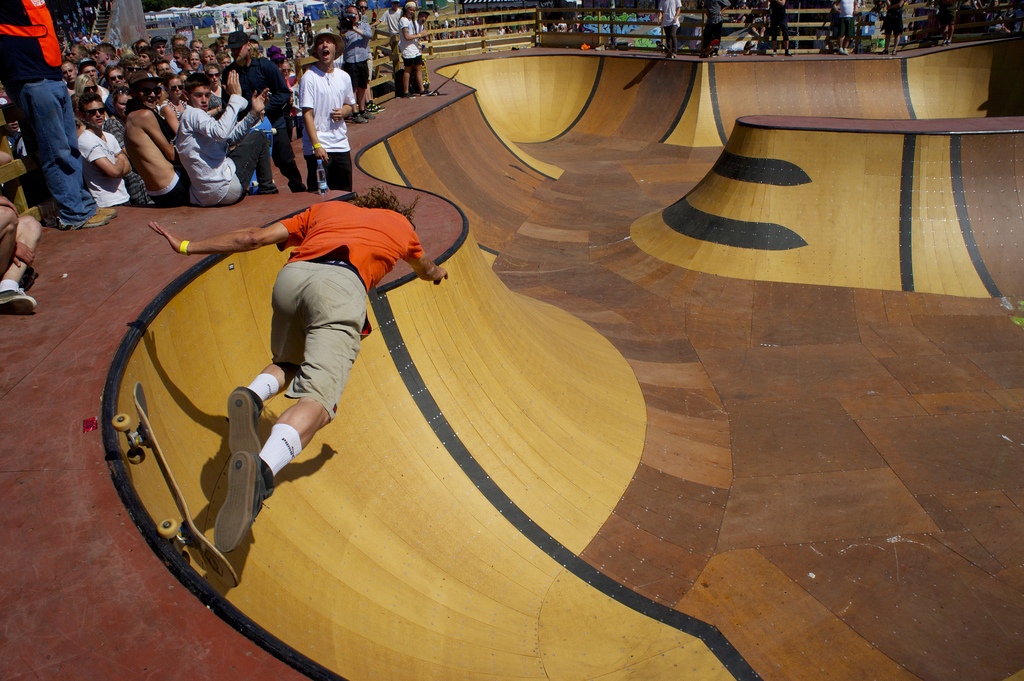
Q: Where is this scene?
A: A skate park.